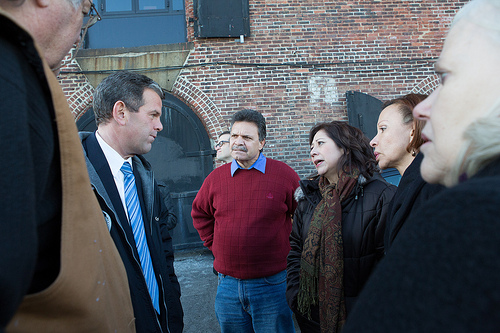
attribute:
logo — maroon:
[264, 192, 274, 200]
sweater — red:
[190, 160, 300, 278]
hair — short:
[93, 70, 165, 120]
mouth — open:
[314, 157, 326, 166]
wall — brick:
[47, 0, 490, 201]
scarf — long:
[299, 175, 367, 332]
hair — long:
[304, 118, 381, 183]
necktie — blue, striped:
[120, 162, 165, 314]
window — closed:
[80, 2, 193, 48]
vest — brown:
[1, 17, 138, 332]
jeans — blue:
[216, 272, 298, 333]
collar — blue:
[229, 153, 267, 177]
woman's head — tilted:
[305, 123, 377, 183]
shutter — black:
[194, 2, 254, 40]